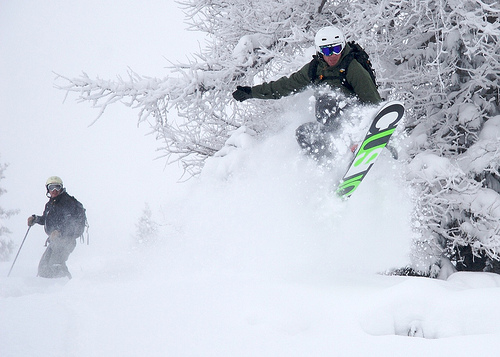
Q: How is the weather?
A: It is overcast.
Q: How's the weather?
A: It is overcast.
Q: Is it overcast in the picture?
A: Yes, it is overcast.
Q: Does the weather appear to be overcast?
A: Yes, it is overcast.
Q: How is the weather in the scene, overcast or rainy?
A: It is overcast.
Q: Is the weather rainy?
A: No, it is overcast.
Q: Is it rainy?
A: No, it is overcast.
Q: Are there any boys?
A: No, there are no boys.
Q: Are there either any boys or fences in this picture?
A: No, there are no boys or fences.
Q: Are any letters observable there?
A: Yes, there are letters.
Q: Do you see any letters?
A: Yes, there are letters.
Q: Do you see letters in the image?
A: Yes, there are letters.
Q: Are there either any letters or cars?
A: Yes, there are letters.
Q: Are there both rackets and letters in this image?
A: No, there are letters but no rackets.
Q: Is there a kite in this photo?
A: No, there are no kites.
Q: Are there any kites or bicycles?
A: No, there are no kites or bicycles.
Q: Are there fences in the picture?
A: No, there are no fences.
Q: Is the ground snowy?
A: Yes, the ground is snowy.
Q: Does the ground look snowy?
A: Yes, the ground is snowy.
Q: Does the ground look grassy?
A: No, the ground is snowy.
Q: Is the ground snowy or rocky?
A: The ground is snowy.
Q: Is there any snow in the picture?
A: Yes, there is snow.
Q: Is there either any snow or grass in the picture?
A: Yes, there is snow.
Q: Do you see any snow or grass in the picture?
A: Yes, there is snow.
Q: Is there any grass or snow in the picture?
A: Yes, there is snow.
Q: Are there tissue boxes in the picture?
A: No, there are no tissue boxes.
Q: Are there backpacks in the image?
A: Yes, there is a backpack.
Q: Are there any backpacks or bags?
A: Yes, there is a backpack.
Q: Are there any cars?
A: No, there are no cars.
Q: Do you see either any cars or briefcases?
A: No, there are no cars or briefcases.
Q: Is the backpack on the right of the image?
A: Yes, the backpack is on the right of the image.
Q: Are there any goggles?
A: Yes, there are goggles.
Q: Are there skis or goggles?
A: Yes, there are goggles.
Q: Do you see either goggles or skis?
A: Yes, there are goggles.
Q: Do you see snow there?
A: Yes, there is snow.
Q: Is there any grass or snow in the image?
A: Yes, there is snow.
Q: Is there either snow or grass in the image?
A: Yes, there is snow.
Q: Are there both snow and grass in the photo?
A: No, there is snow but no grass.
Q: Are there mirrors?
A: No, there are no mirrors.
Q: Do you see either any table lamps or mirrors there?
A: No, there are no mirrors or table lamps.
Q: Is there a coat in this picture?
A: Yes, there is a coat.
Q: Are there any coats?
A: Yes, there is a coat.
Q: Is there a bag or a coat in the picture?
A: Yes, there is a coat.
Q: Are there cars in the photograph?
A: No, there are no cars.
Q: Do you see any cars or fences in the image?
A: No, there are no cars or fences.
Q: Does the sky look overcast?
A: Yes, the sky is overcast.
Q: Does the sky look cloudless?
A: No, the sky is overcast.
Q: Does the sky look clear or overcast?
A: The sky is overcast.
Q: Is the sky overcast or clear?
A: The sky is overcast.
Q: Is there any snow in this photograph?
A: Yes, there is snow.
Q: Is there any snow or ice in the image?
A: Yes, there is snow.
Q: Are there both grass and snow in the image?
A: No, there is snow but no grass.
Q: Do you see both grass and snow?
A: No, there is snow but no grass.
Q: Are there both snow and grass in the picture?
A: No, there is snow but no grass.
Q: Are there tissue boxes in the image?
A: No, there are no tissue boxes.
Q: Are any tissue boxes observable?
A: No, there are no tissue boxes.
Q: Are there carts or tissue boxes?
A: No, there are no tissue boxes or carts.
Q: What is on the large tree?
A: The snow is on the tree.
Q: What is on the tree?
A: The snow is on the tree.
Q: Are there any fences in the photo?
A: No, there are no fences.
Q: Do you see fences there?
A: No, there are no fences.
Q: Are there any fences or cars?
A: No, there are no fences or cars.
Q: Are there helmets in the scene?
A: Yes, there is a helmet.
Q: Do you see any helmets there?
A: Yes, there is a helmet.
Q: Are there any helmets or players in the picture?
A: Yes, there is a helmet.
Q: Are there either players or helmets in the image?
A: Yes, there is a helmet.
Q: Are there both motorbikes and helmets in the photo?
A: No, there is a helmet but no motorcycles.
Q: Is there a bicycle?
A: No, there are no bicycles.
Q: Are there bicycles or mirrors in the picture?
A: No, there are no bicycles or mirrors.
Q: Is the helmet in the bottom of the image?
A: No, the helmet is in the top of the image.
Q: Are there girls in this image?
A: No, there are no girls.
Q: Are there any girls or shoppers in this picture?
A: No, there are no girls or shoppers.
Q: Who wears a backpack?
A: The man wears a backpack.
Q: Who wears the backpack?
A: The man wears a backpack.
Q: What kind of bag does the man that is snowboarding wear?
A: The man wears a backpack.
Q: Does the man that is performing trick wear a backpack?
A: Yes, the man wears a backpack.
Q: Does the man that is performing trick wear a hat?
A: No, the man wears a backpack.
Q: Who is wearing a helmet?
A: The man is wearing a helmet.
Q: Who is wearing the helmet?
A: The man is wearing a helmet.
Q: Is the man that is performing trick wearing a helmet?
A: Yes, the man is wearing a helmet.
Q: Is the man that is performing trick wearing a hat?
A: No, the man is wearing a helmet.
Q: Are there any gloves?
A: Yes, there are gloves.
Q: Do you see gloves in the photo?
A: Yes, there are gloves.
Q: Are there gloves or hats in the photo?
A: Yes, there are gloves.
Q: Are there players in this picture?
A: No, there are no players.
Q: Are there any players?
A: No, there are no players.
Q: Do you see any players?
A: No, there are no players.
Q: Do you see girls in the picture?
A: No, there are no girls.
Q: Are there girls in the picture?
A: No, there are no girls.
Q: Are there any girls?
A: No, there are no girls.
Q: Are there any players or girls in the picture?
A: No, there are no girls or players.